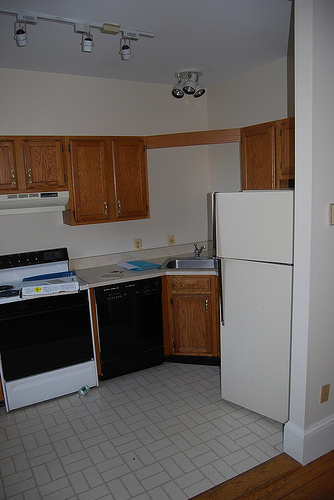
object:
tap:
[193, 242, 207, 258]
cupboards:
[61, 135, 112, 227]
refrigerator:
[210, 188, 294, 425]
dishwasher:
[92, 276, 165, 381]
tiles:
[125, 382, 172, 433]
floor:
[0, 360, 186, 499]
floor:
[185, 449, 334, 498]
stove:
[0, 247, 99, 412]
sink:
[163, 256, 217, 271]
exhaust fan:
[0, 189, 69, 216]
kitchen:
[0, 0, 295, 499]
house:
[0, 0, 333, 500]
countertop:
[67, 238, 219, 290]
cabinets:
[0, 135, 69, 195]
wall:
[0, 65, 213, 262]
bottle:
[74, 384, 89, 398]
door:
[168, 274, 217, 356]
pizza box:
[19, 268, 81, 296]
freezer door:
[210, 190, 292, 265]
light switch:
[166, 233, 176, 246]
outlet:
[133, 236, 143, 252]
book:
[115, 259, 162, 271]